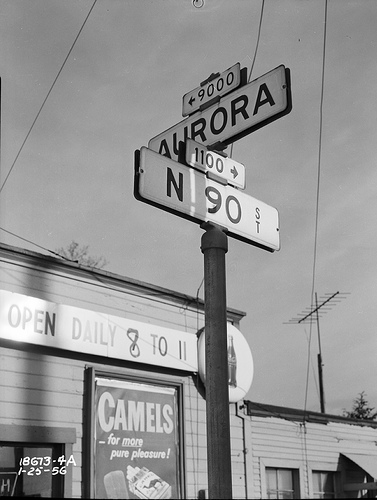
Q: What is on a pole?
A: Signs.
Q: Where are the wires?
A: Above the sign.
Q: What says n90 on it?
A: The sign.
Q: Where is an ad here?
A: On the wall.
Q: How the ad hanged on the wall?
A: Vertically.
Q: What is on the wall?
A: Advertisement poster.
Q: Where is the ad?
A: Wall.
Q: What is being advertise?
A: Cigarette.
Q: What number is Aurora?
A: 9000.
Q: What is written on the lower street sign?
A: N 90 st.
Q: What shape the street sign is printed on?
A: Rectangular.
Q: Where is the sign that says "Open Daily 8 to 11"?
A: Mounted on a wall.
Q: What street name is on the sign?
A: Aurora.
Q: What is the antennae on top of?
A: A roof.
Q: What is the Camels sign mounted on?
A: A building.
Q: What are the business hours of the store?
A: 8 till 11.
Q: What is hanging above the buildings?
A: Power lines.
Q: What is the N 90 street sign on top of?
A: A pole.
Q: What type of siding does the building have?
A: Aluminum siding.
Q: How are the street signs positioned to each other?
A: Crossed.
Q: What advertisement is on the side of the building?
A: Cigarette advertisement.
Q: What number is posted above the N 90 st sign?
A: 1100.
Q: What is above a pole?
A: White signs.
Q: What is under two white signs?
A: A pole.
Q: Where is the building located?
A: Behind black pole.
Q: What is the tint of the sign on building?
A: White.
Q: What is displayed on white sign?
A: Black letters.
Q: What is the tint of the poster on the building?
A: Gray.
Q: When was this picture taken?
A: Daytime.